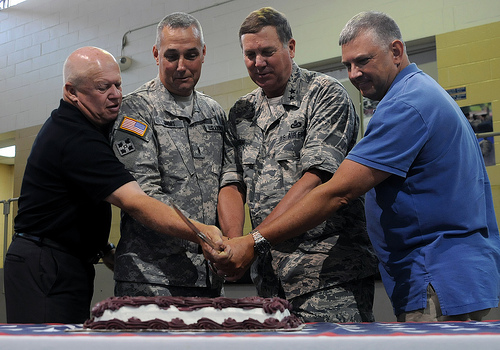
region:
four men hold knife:
[55, 54, 461, 305]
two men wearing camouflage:
[126, 79, 362, 323]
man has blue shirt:
[341, 75, 478, 320]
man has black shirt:
[23, 104, 97, 266]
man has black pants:
[11, 223, 85, 329]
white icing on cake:
[82, 309, 295, 323]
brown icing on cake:
[108, 294, 292, 307]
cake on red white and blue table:
[85, 304, 320, 349]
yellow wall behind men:
[428, 35, 493, 90]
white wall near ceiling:
[3, 8, 58, 113]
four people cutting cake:
[70, 16, 453, 326]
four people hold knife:
[47, 21, 445, 299]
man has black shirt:
[45, 41, 100, 239]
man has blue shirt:
[336, 87, 481, 304]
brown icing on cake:
[94, 302, 296, 335]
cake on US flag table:
[88, 288, 290, 337]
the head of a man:
[322, 8, 429, 110]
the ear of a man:
[382, 28, 419, 66]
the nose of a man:
[340, 66, 370, 86]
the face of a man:
[328, 11, 423, 105]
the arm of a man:
[250, 58, 468, 259]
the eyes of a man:
[332, 46, 383, 77]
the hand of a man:
[211, 219, 291, 273]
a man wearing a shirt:
[147, 28, 378, 313]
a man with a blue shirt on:
[342, 46, 484, 284]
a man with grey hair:
[325, 3, 455, 111]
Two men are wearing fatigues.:
[114, 11, 344, 303]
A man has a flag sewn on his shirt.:
[112, 111, 157, 151]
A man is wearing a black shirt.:
[20, 95, 121, 276]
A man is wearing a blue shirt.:
[371, 102, 483, 296]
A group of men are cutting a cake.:
[43, 75, 497, 268]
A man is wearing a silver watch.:
[250, 224, 276, 274]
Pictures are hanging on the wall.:
[458, 83, 498, 153]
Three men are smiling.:
[147, 48, 414, 143]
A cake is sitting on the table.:
[81, 293, 303, 347]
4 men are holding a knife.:
[54, 59, 443, 294]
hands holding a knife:
[205, 223, 250, 273]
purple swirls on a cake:
[119, 294, 283, 308]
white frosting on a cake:
[120, 303, 276, 319]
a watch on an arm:
[251, 228, 273, 257]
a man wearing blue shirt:
[339, 17, 494, 311]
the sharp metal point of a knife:
[172, 201, 202, 233]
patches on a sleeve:
[117, 113, 151, 156]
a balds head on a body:
[59, 50, 127, 119]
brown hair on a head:
[243, 10, 291, 30]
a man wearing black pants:
[11, 37, 116, 302]